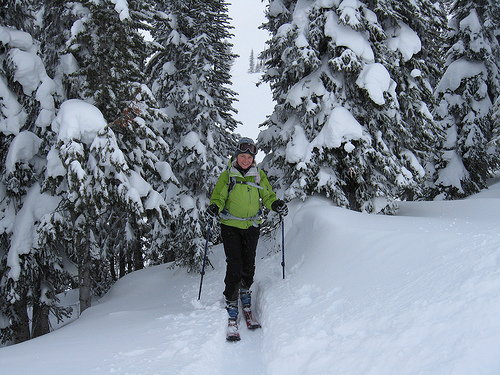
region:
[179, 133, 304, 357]
Woman skiier standing in the snow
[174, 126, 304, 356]
Woman smiling at the camera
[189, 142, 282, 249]
Woman in yellow and white ski jacket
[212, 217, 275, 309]
Black ski pants on skier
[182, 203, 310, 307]
Two black ski poles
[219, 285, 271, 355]
Two black skis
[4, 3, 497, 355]
Trees with snow on top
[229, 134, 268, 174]
Black and grey ski goggles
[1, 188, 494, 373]
Snow on the ground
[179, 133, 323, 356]
Woman with dark hair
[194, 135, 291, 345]
Skier posing for camera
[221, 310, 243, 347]
Foot of smiling skier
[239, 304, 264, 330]
Foot of smiling skier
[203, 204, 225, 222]
Hand of smiling skier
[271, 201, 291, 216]
Hand of smiling skier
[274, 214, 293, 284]
Ski pole of athletic person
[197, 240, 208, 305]
Ski pole of athletic person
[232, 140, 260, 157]
Hat of athletic person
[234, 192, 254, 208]
Part of skier's green jacket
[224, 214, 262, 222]
Part of skier's belt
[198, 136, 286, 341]
A woman dressed in snow gear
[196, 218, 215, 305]
A ski pole is in the snow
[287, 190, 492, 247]
Snow drifts next to trees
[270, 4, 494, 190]
Evergreen trees covered in snow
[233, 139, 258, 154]
Ski goggles on a woman's head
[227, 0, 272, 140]
An opening between two groups of trees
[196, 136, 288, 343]
A woman is cross country skiing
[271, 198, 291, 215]
Thick gloves on a woman's hand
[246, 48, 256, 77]
Tall skinny evergreen tree in the distance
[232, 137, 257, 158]
Gray snow hat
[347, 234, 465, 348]
the snow is white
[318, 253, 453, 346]
the snow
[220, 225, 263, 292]
women is wearing black pants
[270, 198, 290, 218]
a glove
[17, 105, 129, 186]
snow on the tree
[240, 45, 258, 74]
a tree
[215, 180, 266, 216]
the women is wearing a green jacket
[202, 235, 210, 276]
women is carrying ski pole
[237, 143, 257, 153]
ski goggles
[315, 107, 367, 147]
snow on the tree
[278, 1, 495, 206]
snow on pine trees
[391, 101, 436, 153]
snow topped pine needles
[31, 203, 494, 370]
deep snow on ground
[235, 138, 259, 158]
hat on woman's head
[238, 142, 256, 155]
goggles on front of hat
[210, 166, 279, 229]
green winter coat on woman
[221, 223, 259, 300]
black winter pants on legs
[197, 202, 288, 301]
two poles in snow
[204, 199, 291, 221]
top of poles in gloves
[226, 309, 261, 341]
two skis on snow